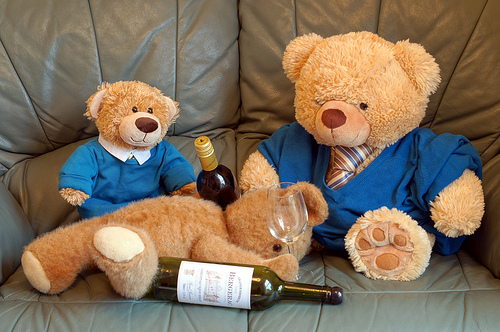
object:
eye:
[359, 102, 370, 111]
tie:
[323, 146, 370, 190]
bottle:
[152, 253, 344, 311]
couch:
[0, 0, 500, 332]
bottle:
[192, 135, 242, 211]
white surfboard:
[177, 260, 255, 310]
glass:
[264, 181, 316, 285]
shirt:
[258, 120, 486, 258]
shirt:
[56, 136, 198, 219]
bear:
[58, 79, 198, 218]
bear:
[20, 181, 328, 302]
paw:
[90, 223, 147, 266]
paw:
[340, 205, 430, 281]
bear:
[239, 29, 483, 282]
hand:
[263, 252, 300, 282]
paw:
[19, 248, 67, 294]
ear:
[281, 32, 322, 84]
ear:
[391, 40, 441, 96]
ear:
[288, 181, 329, 227]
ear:
[85, 90, 107, 120]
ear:
[164, 95, 180, 122]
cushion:
[0, 215, 500, 332]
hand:
[59, 186, 90, 205]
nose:
[321, 108, 348, 129]